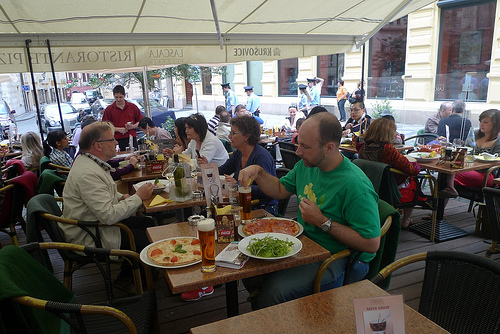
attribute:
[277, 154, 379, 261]
shirt — green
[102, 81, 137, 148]
man — young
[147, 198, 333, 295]
table — brown 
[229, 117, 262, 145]
curly hair —  curly,  gray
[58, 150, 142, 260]
shirt — white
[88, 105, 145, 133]
shirt — red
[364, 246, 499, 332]
chair — empty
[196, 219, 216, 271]
beer — in glass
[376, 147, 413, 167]
red shirt —  red 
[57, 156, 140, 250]
jacket —  khaki colored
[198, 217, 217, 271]
glass — tall 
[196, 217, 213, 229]
foam head — white 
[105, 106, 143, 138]
shirt —  red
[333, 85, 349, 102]
shirt — orange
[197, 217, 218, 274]
beer — in tall glass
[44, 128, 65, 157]
hair — dark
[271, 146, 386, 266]
shirt — green 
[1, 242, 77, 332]
sweater — green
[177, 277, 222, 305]
shoe — red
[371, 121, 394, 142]
hair —   woman's,  blonde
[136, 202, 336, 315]
table — brown 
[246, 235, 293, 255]
vegetables —  green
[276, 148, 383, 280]
shirt — green 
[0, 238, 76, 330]
jacket —  green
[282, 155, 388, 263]
shirt —  man's,  green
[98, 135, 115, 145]
glasses —  black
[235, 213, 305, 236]
plate — white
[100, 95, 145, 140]
polo — red